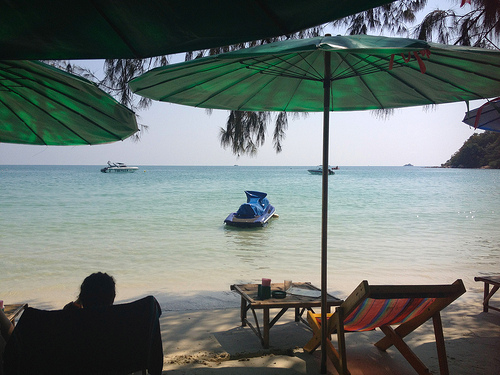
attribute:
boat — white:
[98, 160, 139, 174]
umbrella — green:
[126, 34, 498, 373]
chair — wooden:
[292, 268, 469, 373]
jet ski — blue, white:
[208, 179, 285, 230]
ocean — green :
[3, 164, 493, 259]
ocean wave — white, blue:
[137, 240, 196, 257]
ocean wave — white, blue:
[155, 220, 205, 227]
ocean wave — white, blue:
[229, 247, 291, 263]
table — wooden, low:
[223, 275, 341, 353]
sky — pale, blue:
[165, 103, 337, 173]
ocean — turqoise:
[94, 163, 481, 278]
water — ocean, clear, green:
[11, 162, 478, 278]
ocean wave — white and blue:
[388, 205, 426, 220]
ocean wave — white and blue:
[424, 216, 470, 225]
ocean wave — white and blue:
[433, 197, 481, 222]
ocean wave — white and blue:
[366, 214, 379, 220]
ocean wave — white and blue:
[420, 204, 448, 214]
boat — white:
[96, 155, 141, 182]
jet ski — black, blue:
[225, 190, 277, 227]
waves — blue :
[60, 196, 168, 258]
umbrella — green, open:
[1, 61, 141, 149]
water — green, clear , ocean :
[349, 223, 369, 240]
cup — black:
[255, 281, 272, 301]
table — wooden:
[229, 282, 344, 347]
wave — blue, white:
[27, 189, 117, 233]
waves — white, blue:
[101, 184, 180, 219]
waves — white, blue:
[358, 164, 464, 263]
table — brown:
[231, 276, 344, 346]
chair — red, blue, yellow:
[300, 277, 467, 373]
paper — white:
[285, 284, 323, 299]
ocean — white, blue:
[0, 164, 497, 296]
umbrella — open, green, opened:
[128, 35, 498, 150]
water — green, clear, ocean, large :
[3, 160, 498, 295]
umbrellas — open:
[2, 39, 492, 285]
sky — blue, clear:
[353, 113, 425, 151]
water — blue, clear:
[398, 202, 464, 247]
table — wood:
[274, 292, 327, 314]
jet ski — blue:
[219, 187, 279, 227]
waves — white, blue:
[334, 189, 484, 254]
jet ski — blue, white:
[222, 190, 277, 230]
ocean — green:
[0, 165, 494, 314]